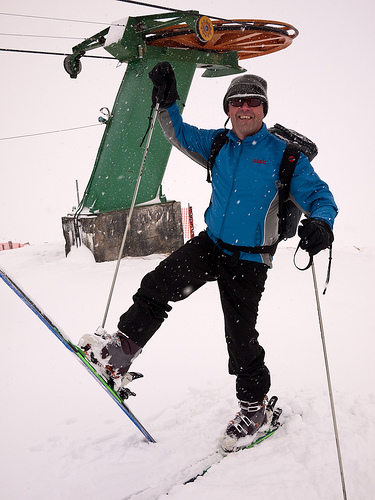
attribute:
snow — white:
[1, 237, 374, 497]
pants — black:
[116, 229, 277, 401]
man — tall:
[206, 71, 269, 215]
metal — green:
[74, 7, 263, 248]